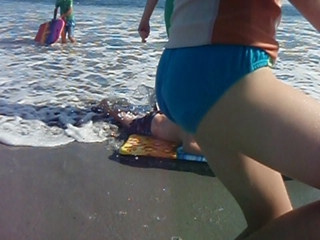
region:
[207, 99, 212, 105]
edge fo a pnty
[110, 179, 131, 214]
part f a beach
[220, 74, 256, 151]
part of a shade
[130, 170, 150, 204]
part fo a geround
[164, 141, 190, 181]
ede of a boared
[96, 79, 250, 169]
Person laying on the beach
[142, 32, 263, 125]
person wearing swimming trunks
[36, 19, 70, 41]
person holding a pink surfboard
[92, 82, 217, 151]
person swimming in the ocean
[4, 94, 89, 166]
water washing up ashore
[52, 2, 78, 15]
person wearing a green shirt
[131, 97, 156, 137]
person wearing black shore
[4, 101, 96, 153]
water washing up on beach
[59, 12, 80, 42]
person wearing blue shorts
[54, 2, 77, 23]
person wearing a green shirt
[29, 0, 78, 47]
person standing in water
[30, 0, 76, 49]
person holding striped boogie board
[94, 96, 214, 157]
person laying in water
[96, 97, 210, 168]
person laying on water's edge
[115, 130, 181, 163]
yellow area of boogie board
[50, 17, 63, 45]
pink end on boogie board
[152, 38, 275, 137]
bottom area of blue swimsuit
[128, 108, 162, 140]
dark brown swim trunks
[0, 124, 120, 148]
edge of frothy water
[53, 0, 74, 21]
green casual tee shirt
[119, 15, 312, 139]
a man wearing drawyer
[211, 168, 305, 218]
leg of the person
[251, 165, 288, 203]
light on the leg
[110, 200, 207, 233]
white marks in the ground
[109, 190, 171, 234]
white marks in the sand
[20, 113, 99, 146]
a flow of water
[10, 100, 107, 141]
water coming in to sand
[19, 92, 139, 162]
water coming out of the ocean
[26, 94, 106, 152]
water coming out of the sea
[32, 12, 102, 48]
a man in the water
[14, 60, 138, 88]
White foam floating in the water.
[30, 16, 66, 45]
A pink multi colored surfing board.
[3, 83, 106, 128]
A surfer's shadows on the water.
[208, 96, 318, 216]
The legs of a surfer.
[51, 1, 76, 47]
A man wearing a green shirt.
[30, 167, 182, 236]
A wet sandy brown beach.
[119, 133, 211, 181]
A colorful floatation device.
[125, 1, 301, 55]
A surfer's green and white shirt.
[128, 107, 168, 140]
Butt cleavage holding black swimming trunks.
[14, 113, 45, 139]
the water is white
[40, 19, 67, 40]
a board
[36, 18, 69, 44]
a boogie board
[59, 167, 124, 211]
the sand is wet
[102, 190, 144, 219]
the wet sand on the beach